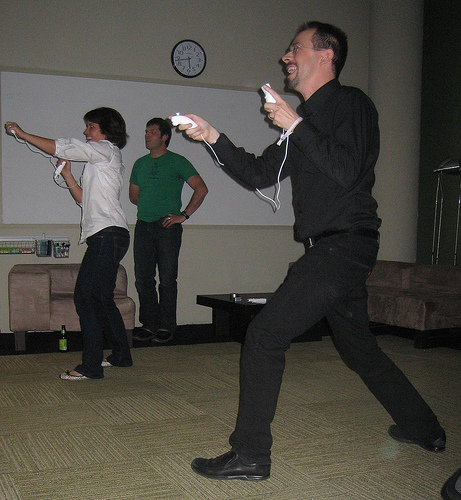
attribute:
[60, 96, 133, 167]
woman — smiling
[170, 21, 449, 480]
male — engaged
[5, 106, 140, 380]
female — engaged, dark haired,  Dark haired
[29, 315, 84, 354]
bottle — green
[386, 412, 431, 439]
dark shoe — colored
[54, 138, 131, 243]
shirt — white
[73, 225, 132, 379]
pants — black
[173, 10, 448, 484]
man — laughing, caucasian, smiling, playing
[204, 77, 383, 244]
shirt — black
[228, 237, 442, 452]
pants — black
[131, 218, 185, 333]
pants — black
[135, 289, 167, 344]
shoe —  guy's,  foot's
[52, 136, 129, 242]
white shirt —  white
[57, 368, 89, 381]
shoe —  casual dress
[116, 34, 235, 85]
clock — for wall, 5:44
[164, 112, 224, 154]
wii controller — white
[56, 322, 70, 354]
bottle — green,  green labeled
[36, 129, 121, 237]
blouse — white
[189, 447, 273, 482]
shoe —  black,  foot's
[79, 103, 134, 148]
hair — short, dark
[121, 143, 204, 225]
shirt — green